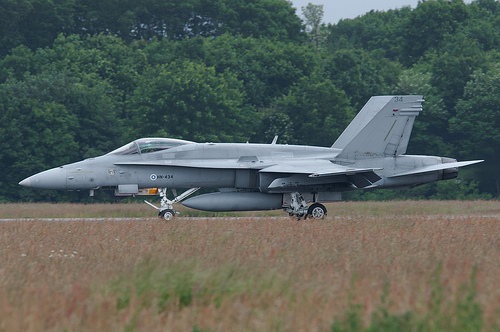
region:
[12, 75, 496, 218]
a military plane on a runway at a remote airport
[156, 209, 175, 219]
small front wheel on the plane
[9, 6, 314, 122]
dense green forest beyond the plane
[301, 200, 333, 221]
large back tire on the plane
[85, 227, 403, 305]
very brown and green grassy area in front of the plane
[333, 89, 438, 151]
large grey tail on the plane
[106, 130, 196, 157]
streamlined glass enclosure over the cockpit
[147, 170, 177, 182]
identification numbering on the side of the plane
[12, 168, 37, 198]
the pointed tip at the front of the plane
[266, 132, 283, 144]
a very small rudder coming up from the middle of the plane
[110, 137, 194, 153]
the cockpit of the plane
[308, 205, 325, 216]
the wheel on the airplane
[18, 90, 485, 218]
an airplane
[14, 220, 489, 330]
tall grass in front of the plane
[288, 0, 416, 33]
the sky through the trees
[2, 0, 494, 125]
a thick brush of trees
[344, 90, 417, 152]
the wings on the back of the plane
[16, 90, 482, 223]
a silver airplane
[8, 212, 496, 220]
a strip of asphalt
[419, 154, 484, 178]
the propeller on the back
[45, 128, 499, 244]
this is a jet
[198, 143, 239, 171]
the jet is white in color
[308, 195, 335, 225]
this is the wheel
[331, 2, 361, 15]
this is the sky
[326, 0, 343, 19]
the sky is blue in color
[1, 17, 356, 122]
this is a forest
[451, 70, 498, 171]
this is a tree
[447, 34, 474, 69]
the leaves are green in color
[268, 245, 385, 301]
this is a grass area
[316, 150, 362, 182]
this is the wing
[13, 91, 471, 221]
a sleek fighter jet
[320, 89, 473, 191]
the tail to a fighter jet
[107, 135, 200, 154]
a fighter jet cockpit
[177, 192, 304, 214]
a missile strapped to a jet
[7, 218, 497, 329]
a lush green and orange field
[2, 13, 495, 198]
a jet in the forefront of a forest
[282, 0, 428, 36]
a cloudy sky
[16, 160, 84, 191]
the nosecone of a jet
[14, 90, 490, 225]
a long gray jet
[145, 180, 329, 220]
the wheels of a jet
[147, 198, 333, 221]
the wheels of the jet on the ground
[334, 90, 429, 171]
the tail wings of the jet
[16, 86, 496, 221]
the fighter jet on the runway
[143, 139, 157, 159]
the pilot in the cockpit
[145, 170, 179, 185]
the marking on the belly of the plane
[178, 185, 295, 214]
the missle on the bottom of the jet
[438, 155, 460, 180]
the flame exhaust on the back of the jet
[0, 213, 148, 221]
the runway pavement between the fields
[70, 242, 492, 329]
green gras in the brown field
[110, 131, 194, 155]
the windshield for the pilots cockpit